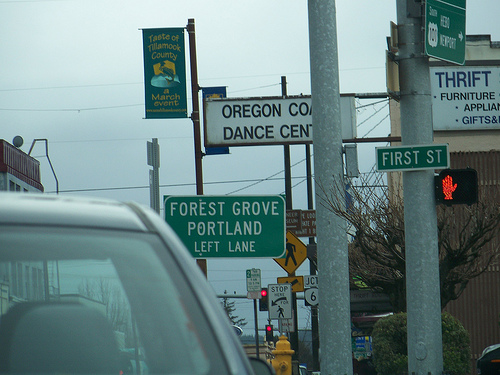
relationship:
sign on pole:
[376, 144, 450, 173] [396, 0, 444, 374]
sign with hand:
[436, 170, 479, 203] [440, 175, 457, 199]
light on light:
[261, 289, 267, 296] [261, 291, 267, 296]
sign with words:
[162, 194, 287, 260] [171, 202, 278, 251]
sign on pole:
[207, 98, 311, 141] [203, 93, 312, 148]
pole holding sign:
[396, 0, 444, 374] [376, 144, 450, 173]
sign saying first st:
[376, 144, 450, 173] [383, 151, 443, 168]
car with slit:
[0, 191, 248, 373] [123, 202, 158, 234]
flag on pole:
[143, 28, 187, 120] [187, 17, 208, 264]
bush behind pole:
[442, 312, 478, 374] [396, 0, 444, 374]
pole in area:
[280, 76, 299, 373] [2, 0, 498, 373]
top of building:
[0, 141, 44, 235] [0, 142, 45, 192]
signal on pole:
[436, 170, 479, 203] [396, 0, 444, 374]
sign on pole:
[143, 28, 187, 120] [187, 17, 208, 264]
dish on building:
[14, 134, 24, 148] [0, 142, 45, 192]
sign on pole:
[247, 269, 261, 301] [253, 298, 261, 364]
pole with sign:
[396, 0, 444, 374] [423, 1, 468, 65]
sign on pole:
[423, 1, 468, 65] [396, 0, 444, 374]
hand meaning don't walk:
[440, 175, 457, 199] [436, 170, 479, 203]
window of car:
[0, 225, 230, 373] [0, 191, 248, 373]